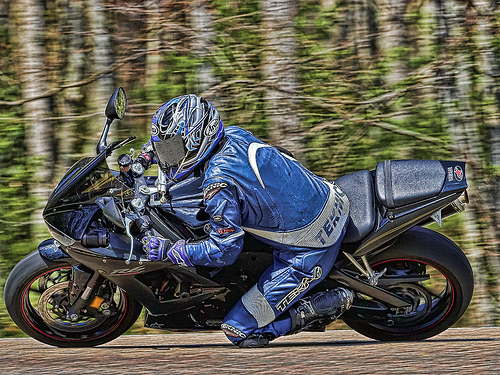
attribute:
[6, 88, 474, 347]
motorcycle — black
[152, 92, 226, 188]
helmet — blue, black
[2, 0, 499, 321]
trees — blurry, green, thin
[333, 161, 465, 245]
seat — blue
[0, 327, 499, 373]
road — gray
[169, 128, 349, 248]
jacket — leather, blue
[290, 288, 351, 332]
boot — black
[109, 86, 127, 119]
mirror — black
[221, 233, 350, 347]
pants — leather, blue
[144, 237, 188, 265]
gloves — blue